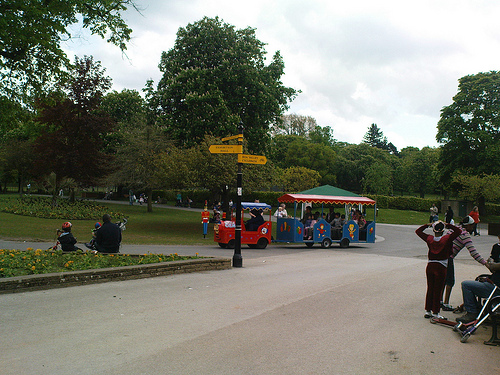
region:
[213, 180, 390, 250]
a train with people riding it.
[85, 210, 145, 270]
a person sitting in a park.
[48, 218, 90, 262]
a person in a park.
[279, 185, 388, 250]
a passenger car on a train.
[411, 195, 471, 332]
A man standing in a park.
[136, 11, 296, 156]
a large leafy green tree.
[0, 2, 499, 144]
a cloud filled sky.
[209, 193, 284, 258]
a train engine on a train.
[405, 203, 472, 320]
A couple of people standing near a road.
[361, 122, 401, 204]
a tall green tree.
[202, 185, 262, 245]
small and red train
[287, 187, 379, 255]
blue and red trolley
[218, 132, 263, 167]
yellow and black signs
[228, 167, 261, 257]
signs on black pole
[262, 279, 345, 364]
sidewalk is light brown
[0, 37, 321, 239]
green trees behind trolley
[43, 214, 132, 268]
people sitting on curb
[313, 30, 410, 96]
white and grey sky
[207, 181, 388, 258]
kids train is being pulled by a red cart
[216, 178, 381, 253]
brightly colored train pulled by a red car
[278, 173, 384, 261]
train has a brightly colored awning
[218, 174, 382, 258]
red car is pulling the train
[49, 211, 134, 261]
people are lounding next to the grass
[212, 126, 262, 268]
black post with yellow street signs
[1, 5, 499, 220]
tall trees surround the park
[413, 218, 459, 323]
woman is standing with her hands on head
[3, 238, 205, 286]
grass has many yellow flowers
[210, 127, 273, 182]
yellow sign has black lettering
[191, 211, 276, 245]
a small red kiddy train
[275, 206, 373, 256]
a small blue kiddy train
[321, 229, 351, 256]
the wheels of a kiddy train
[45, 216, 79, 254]
a little boy sitting down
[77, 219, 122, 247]
an adult sitting down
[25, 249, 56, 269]
a patch of yellow flowers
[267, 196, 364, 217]
the canopy of a kiddy train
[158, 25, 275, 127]
a tall and big green tree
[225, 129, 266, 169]
a bunch of yellow and black signs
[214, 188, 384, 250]
Children's train on the street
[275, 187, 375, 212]
Red roof on the car.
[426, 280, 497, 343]
Scooters by the people.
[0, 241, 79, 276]
Yellow flowers on the ground.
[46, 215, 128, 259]
People sitting down on the brick.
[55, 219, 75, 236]
red helmet on the head.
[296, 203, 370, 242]
People in the train car.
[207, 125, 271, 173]
Yellow signs on the post.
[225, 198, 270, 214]
blue roof on train engine.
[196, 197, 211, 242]
Soldier character in the grass.